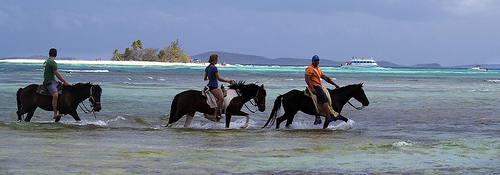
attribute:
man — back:
[18, 46, 80, 120]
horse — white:
[157, 79, 269, 122]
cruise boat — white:
[316, 50, 384, 79]